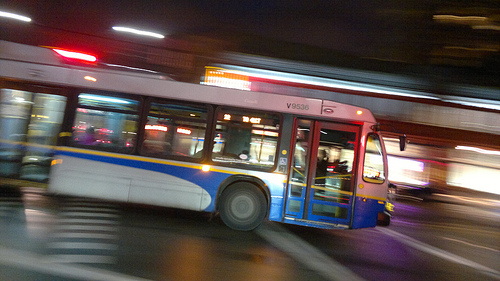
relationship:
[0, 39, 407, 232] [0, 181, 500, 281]
bus traveling down down street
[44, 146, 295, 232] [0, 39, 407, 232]
blue stripe on bus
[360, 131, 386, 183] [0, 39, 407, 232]
window on bus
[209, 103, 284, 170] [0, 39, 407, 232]
window on bus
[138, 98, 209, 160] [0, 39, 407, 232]
this is the window on bus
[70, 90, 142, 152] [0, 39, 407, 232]
window on bus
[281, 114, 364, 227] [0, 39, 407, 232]
bus is closed on bus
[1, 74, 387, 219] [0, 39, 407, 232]
glare on side of bus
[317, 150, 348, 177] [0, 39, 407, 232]
driver sitting on bus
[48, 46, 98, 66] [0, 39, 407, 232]
light above bus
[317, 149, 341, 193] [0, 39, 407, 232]
driver on bus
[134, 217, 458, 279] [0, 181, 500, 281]
painted on street painted on down street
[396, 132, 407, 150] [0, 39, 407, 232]
mirror on bus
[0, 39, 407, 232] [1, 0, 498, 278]
bus moving into intersection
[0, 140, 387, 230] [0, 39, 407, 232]
trim on bus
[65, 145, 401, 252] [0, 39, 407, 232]
yellow stripe on bus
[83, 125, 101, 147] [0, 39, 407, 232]
person sitting on bus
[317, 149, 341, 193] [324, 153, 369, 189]
driver holding steering wheel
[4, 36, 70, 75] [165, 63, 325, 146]
air conditioning put on the bus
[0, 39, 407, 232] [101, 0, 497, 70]
bus runs near an overpass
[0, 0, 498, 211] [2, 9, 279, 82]
near an overpass has lights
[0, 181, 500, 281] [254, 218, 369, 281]
down street has lines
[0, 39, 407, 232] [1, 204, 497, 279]
bus on street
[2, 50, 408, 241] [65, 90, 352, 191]
bus has windows on the bus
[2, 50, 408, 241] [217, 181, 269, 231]
bus has part of a wheel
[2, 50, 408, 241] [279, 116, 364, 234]
bus has door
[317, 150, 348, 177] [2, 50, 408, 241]
driver in bus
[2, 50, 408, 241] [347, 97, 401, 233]
bus has front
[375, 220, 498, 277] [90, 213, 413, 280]
line on street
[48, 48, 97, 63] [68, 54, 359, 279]
light in photo